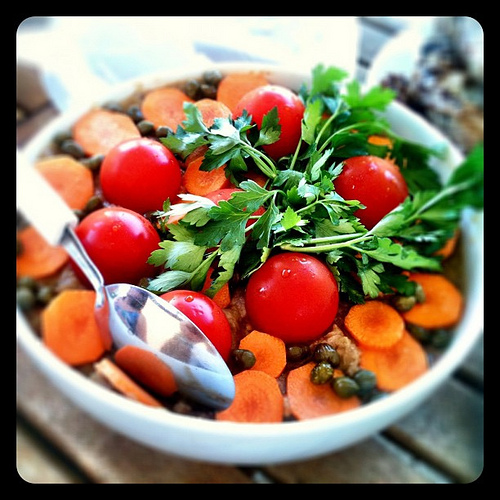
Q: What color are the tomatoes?
A: Red.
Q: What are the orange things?
A: Carrots.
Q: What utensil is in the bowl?
A: Spoon.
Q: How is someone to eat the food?
A: With the spoon.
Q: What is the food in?
A: Bowl.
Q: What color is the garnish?
A: Green.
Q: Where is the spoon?
A: In the bowl.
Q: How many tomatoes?
A: Six.